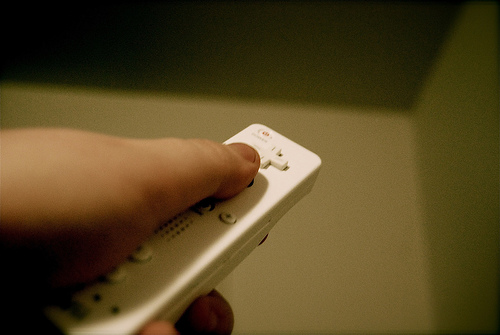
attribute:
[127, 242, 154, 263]
button — circular 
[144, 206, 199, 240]
holes — small 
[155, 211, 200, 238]
openings — remote control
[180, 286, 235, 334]
finger — curled under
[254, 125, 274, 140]
sign — red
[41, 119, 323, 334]
controller — white, wii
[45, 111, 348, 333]
remote control — white 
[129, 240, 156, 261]
button — white